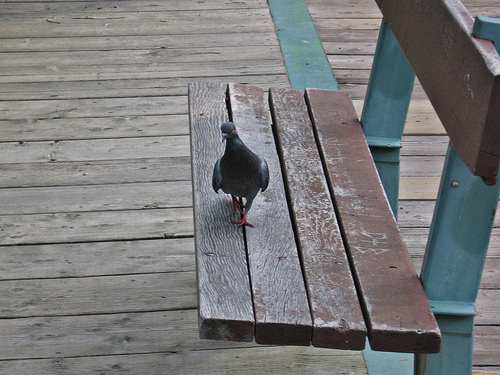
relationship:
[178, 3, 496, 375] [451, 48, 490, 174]
bench made of boards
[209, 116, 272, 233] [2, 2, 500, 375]
dove looking camera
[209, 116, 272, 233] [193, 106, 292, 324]
pigeon walking forward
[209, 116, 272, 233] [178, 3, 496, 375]
bird on a bench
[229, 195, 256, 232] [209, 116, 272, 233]
feet of bird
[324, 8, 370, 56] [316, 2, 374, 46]
part of ground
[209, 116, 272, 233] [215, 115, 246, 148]
bird has head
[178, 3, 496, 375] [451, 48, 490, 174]
bench has boards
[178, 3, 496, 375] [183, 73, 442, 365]
bench has wood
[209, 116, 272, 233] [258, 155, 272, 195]
bird has right wing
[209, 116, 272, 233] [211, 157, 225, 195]
bird has left wing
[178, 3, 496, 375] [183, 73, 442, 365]
bench has top board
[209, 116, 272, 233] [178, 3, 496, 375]
bird on bench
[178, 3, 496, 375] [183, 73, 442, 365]
bench made of wood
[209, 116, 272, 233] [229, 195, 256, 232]
bird has red feet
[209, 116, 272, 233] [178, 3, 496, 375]
pigeon standing on bench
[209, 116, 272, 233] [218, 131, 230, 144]
bird has grey beak